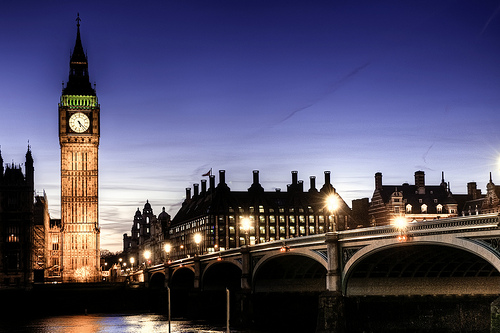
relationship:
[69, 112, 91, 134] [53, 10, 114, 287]
clock on top of tower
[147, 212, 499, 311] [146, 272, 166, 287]
bridge with arch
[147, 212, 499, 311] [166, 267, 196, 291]
bridge with arch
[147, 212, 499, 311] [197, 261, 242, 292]
bridge with arch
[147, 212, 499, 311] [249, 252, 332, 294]
bridge with arch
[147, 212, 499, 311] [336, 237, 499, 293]
bridge with arch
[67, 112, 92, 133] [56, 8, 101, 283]
clock in tower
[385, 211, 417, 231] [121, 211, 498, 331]
light on bridge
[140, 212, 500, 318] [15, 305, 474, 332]
bridge over water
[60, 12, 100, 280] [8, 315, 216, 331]
clock tower over looking water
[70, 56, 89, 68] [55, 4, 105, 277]
lights lighting up tower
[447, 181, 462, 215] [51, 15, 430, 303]
turret on a building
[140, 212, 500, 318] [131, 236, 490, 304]
bridge with arches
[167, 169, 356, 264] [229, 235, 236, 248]
building with window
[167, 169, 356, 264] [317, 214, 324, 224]
building with window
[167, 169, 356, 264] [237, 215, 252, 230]
building with window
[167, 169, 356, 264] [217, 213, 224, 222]
building with window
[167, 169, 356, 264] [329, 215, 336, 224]
building with window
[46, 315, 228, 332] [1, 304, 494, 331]
lights reflection in water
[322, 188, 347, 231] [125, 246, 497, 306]
light attached to bridge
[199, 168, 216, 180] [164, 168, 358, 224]
flag on top of roof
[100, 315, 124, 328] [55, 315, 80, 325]
blue light on water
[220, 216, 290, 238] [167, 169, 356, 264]
windows on building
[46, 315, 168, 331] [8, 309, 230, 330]
lights reflection on water